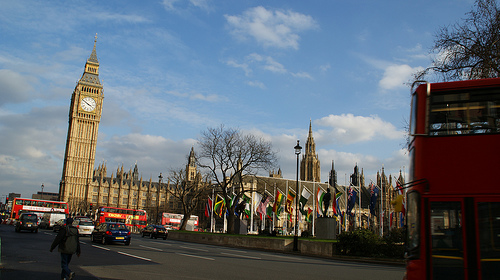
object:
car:
[75, 219, 96, 236]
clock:
[78, 96, 96, 113]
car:
[90, 221, 132, 246]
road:
[0, 224, 413, 280]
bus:
[392, 79, 497, 279]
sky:
[142, 13, 282, 66]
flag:
[201, 186, 215, 217]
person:
[48, 217, 81, 279]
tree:
[188, 123, 280, 236]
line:
[116, 249, 154, 262]